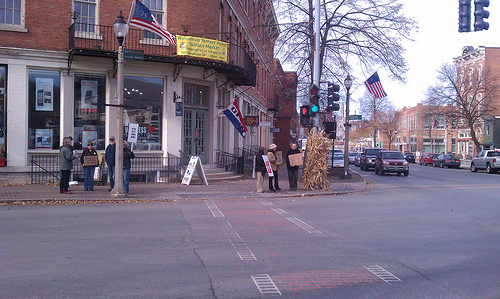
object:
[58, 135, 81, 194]
people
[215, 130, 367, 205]
corner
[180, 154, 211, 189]
sign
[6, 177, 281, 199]
sidewalk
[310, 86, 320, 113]
traffic light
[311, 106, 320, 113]
green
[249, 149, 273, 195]
person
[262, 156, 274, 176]
white and red sign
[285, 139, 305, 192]
person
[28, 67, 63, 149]
window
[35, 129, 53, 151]
posters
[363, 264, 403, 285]
lines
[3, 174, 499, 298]
street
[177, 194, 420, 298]
crosswalk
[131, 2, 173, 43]
flag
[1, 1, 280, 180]
building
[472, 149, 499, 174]
car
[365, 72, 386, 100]
flag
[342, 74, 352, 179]
lamppost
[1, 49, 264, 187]
storefront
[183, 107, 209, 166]
grey doors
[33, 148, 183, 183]
railing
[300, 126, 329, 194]
corn stalks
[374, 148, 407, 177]
car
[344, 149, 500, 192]
street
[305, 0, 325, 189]
pole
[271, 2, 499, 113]
sky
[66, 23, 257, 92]
railing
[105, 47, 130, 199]
lamppost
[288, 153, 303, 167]
sign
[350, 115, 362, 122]
street sign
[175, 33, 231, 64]
banner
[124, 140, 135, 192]
person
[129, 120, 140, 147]
picket sign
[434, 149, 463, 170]
car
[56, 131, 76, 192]
person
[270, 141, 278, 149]
cap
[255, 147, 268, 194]
people